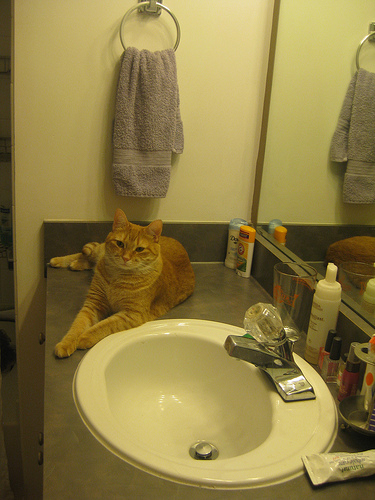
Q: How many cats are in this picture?
A: One.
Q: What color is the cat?
A: Orange.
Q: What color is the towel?
A: Gray.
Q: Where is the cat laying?
A: On the sink counter.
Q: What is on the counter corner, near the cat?
A: Deodorant.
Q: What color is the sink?
A: White.